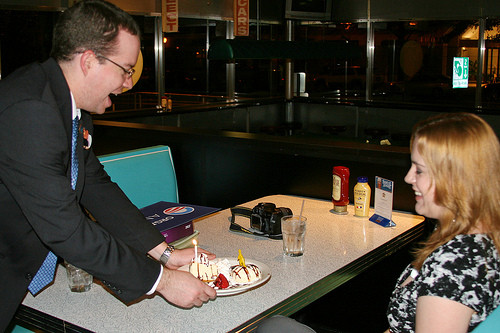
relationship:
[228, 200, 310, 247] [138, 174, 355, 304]
camera sitting on table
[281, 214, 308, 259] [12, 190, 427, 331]
drink sitting on table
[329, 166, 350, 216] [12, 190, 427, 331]
bottle sitting on table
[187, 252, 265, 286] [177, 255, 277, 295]
desert on a plate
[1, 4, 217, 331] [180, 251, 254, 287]
man placing a desert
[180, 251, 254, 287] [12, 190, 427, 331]
desert on a table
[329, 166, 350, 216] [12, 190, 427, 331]
bottle turned on table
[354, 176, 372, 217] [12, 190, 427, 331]
bottle turned on table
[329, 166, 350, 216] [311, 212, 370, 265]
bottle turned on table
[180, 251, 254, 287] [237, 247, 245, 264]
desert surprise with candle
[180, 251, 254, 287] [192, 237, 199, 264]
desert surprise with candle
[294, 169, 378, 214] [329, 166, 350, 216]
bottle of bottle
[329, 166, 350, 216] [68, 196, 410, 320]
bottle on table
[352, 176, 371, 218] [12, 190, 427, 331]
bottle on table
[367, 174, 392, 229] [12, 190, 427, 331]
menu on table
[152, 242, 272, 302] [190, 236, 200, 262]
plate with a candle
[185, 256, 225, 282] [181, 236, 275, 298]
cake on a plate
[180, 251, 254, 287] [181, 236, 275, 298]
desert on a plate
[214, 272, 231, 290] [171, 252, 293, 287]
strawberry on a plate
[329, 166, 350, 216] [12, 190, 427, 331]
bottle on a table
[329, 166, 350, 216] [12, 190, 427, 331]
bottle turned upside down on table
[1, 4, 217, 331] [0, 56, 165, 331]
man in suit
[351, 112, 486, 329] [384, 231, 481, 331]
woman in top